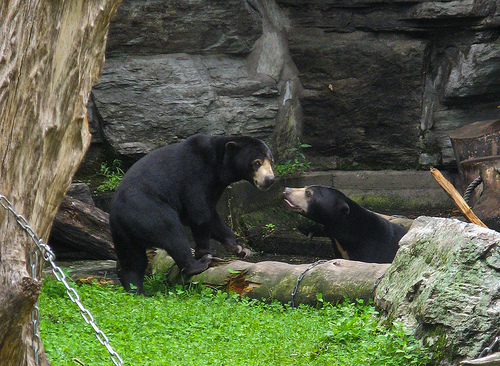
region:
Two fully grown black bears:
[83, 92, 448, 307]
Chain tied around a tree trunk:
[0, 172, 130, 364]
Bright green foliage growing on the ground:
[91, 281, 394, 361]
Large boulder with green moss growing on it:
[369, 198, 499, 356]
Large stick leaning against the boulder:
[420, 147, 495, 259]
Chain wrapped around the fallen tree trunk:
[284, 254, 338, 311]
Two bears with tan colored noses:
[210, 120, 350, 232]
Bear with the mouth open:
[280, 162, 337, 240]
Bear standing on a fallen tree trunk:
[107, 130, 279, 298]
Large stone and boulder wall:
[103, 4, 491, 128]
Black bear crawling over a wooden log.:
[96, 124, 281, 298]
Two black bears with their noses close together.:
[96, 113, 431, 288]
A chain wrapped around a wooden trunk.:
[2, 170, 131, 363]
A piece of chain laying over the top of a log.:
[272, 250, 339, 310]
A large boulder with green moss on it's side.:
[366, 203, 498, 363]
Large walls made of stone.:
[112, 6, 497, 150]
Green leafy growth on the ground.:
[57, 289, 371, 364]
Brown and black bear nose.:
[251, 168, 283, 190]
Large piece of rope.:
[452, 164, 496, 207]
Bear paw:
[226, 237, 263, 259]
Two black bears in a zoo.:
[107, 131, 408, 306]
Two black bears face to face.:
[110, 131, 406, 293]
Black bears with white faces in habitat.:
[0, 1, 498, 363]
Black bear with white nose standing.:
[107, 131, 277, 294]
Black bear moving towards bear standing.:
[283, 184, 409, 261]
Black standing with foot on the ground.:
[106, 134, 276, 296]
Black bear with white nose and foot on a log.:
[110, 130, 275, 293]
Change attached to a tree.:
[0, 192, 143, 364]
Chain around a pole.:
[273, 257, 383, 306]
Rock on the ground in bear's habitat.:
[372, 212, 498, 362]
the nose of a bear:
[264, 172, 277, 185]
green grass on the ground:
[27, 267, 439, 364]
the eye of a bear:
[302, 187, 313, 199]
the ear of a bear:
[340, 198, 354, 215]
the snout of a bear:
[248, 164, 277, 192]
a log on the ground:
[223, 257, 396, 307]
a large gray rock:
[359, 215, 499, 364]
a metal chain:
[0, 190, 132, 365]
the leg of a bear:
[114, 237, 151, 297]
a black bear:
[108, 127, 276, 299]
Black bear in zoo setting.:
[98, 116, 276, 303]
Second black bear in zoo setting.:
[284, 137, 456, 308]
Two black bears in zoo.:
[111, 129, 396, 308]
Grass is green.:
[37, 283, 399, 364]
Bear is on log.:
[110, 126, 284, 299]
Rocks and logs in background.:
[2, 7, 498, 290]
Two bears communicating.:
[112, 129, 399, 291]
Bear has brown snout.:
[102, 125, 273, 287]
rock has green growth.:
[375, 213, 498, 360]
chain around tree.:
[2, 192, 125, 364]